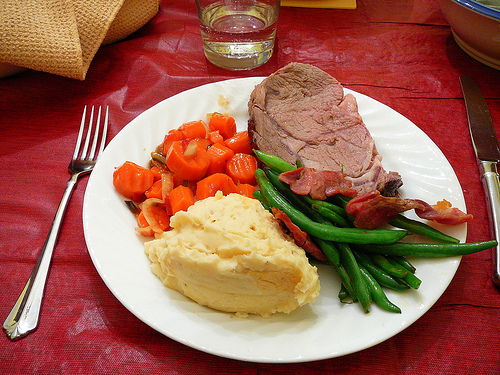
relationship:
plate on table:
[392, 111, 462, 190] [358, 16, 464, 115]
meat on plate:
[257, 66, 369, 162] [392, 111, 462, 190]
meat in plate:
[257, 66, 369, 162] [392, 111, 462, 190]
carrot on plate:
[157, 127, 243, 192] [392, 111, 462, 190]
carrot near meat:
[157, 127, 243, 192] [257, 66, 369, 162]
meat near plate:
[257, 66, 369, 162] [392, 111, 462, 190]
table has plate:
[358, 16, 464, 115] [392, 111, 462, 190]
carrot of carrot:
[112, 112, 257, 234] [157, 127, 243, 192]